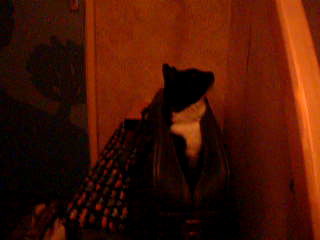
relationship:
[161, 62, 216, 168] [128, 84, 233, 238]
cat in bag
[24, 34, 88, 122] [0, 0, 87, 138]
tree on wall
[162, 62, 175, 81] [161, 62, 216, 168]
ear of cat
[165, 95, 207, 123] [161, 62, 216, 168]
neck of cat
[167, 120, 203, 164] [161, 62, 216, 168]
chest of cat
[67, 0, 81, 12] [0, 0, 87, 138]
thermostat on wall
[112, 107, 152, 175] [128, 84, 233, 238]
strap on bag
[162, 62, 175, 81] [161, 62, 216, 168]
ear on cat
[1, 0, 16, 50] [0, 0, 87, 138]
spot on wall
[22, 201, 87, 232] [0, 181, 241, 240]
items on table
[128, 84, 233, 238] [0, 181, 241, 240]
bag on table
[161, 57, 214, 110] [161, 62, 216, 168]
head of cat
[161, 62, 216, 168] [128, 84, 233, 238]
cat inside bag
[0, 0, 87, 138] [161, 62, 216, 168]
wall behind cat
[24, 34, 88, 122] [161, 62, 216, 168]
tree behind cat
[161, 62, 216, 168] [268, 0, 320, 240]
cat looks at rail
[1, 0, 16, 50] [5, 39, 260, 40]
spot in background